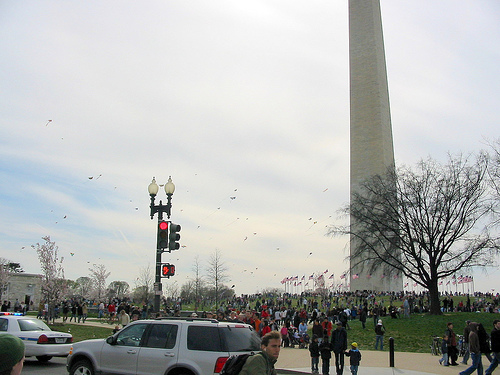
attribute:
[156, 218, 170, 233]
light — red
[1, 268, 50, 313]
building — on left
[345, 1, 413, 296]
monument — washington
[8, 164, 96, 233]
sky — cloudy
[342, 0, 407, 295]
cement monument — large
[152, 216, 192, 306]
sign — illuminated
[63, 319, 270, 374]
suv — white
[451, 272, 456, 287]
flag — american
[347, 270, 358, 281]
flag — american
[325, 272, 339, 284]
flag — american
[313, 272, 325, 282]
flag — american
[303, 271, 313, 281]
flag — american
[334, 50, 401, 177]
monument — war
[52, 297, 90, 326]
people — walking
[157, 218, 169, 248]
traffic light — red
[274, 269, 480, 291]
flags — american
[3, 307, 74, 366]
police car — white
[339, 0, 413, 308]
monumnet — washington dc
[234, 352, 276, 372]
parka — green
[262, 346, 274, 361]
earbuds — white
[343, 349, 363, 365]
coat — blue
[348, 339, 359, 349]
hat — yellow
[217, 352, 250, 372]
backpack — black